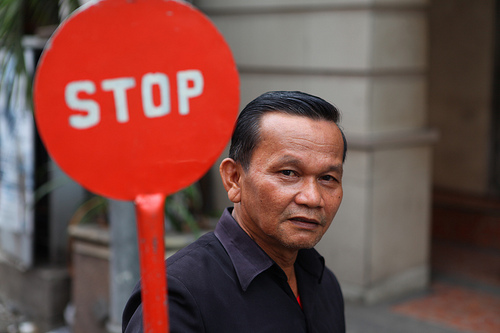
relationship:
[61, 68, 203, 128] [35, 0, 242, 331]
word on sign